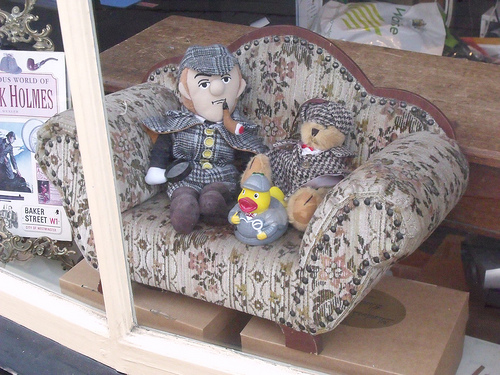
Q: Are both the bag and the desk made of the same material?
A: No, the bag is made of plastic and the desk is made of wood.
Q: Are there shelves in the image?
A: No, there are no shelves.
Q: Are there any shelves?
A: No, there are no shelves.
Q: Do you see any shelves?
A: No, there are no shelves.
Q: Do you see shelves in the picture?
A: No, there are no shelves.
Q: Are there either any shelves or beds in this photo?
A: No, there are no shelves or beds.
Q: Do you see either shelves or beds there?
A: No, there are no shelves or beds.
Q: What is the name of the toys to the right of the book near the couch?
A: The toys are stuffed animals.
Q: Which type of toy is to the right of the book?
A: The toys are stuffed animals.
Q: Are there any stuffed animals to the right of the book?
A: Yes, there are stuffed animals to the right of the book.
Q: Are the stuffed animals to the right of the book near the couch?
A: Yes, the stuffed animals are to the right of the book.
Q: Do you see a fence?
A: No, there are no fences.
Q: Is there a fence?
A: No, there are no fences.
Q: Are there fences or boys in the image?
A: No, there are no fences or boys.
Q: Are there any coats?
A: Yes, there is a coat.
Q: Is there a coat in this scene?
A: Yes, there is a coat.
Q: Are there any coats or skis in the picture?
A: Yes, there is a coat.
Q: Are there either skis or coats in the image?
A: Yes, there is a coat.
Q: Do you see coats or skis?
A: Yes, there is a coat.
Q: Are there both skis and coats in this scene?
A: No, there is a coat but no skis.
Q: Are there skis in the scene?
A: No, there are no skis.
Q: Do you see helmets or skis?
A: No, there are no skis or helmets.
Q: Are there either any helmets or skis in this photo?
A: No, there are no skis or helmets.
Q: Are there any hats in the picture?
A: Yes, there is a hat.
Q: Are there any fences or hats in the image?
A: Yes, there is a hat.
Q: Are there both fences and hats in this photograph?
A: No, there is a hat but no fences.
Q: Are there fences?
A: No, there are no fences.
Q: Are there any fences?
A: No, there are no fences.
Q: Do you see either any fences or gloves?
A: No, there are no fences or gloves.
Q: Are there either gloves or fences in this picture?
A: No, there are no fences or gloves.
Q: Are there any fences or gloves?
A: No, there are no fences or gloves.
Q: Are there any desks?
A: Yes, there is a desk.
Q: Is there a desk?
A: Yes, there is a desk.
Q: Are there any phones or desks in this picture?
A: Yes, there is a desk.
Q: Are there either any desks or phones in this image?
A: Yes, there is a desk.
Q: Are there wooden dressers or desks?
A: Yes, there is a wood desk.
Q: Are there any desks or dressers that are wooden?
A: Yes, the desk is wooden.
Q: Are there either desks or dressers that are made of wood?
A: Yes, the desk is made of wood.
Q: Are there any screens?
A: No, there are no screens.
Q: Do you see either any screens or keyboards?
A: No, there are no screens or keyboards.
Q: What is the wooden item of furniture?
A: The piece of furniture is a desk.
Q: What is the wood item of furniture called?
A: The piece of furniture is a desk.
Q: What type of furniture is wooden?
A: The furniture is a desk.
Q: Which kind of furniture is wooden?
A: The furniture is a desk.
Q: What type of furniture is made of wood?
A: The furniture is a desk.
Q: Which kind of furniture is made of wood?
A: The furniture is a desk.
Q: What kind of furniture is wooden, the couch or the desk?
A: The desk is wooden.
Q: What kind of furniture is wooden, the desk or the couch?
A: The desk is wooden.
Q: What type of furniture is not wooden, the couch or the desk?
A: The couch is not wooden.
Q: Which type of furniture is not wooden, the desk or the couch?
A: The couch is not wooden.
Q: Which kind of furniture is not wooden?
A: The furniture is a couch.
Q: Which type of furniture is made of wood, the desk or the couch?
A: The desk is made of wood.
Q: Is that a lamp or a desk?
A: That is a desk.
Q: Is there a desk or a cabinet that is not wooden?
A: No, there is a desk but it is wooden.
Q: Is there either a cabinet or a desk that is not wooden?
A: No, there is a desk but it is wooden.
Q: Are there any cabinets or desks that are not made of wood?
A: No, there is a desk but it is made of wood.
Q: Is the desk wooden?
A: Yes, the desk is wooden.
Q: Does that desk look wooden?
A: Yes, the desk is wooden.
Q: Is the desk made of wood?
A: Yes, the desk is made of wood.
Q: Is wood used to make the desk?
A: Yes, the desk is made of wood.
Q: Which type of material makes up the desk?
A: The desk is made of wood.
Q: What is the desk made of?
A: The desk is made of wood.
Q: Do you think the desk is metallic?
A: No, the desk is wooden.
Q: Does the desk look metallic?
A: No, the desk is wooden.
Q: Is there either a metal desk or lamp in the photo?
A: No, there is a desk but it is wooden.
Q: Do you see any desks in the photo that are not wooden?
A: No, there is a desk but it is wooden.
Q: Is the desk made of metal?
A: No, the desk is made of wood.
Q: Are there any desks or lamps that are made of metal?
A: No, there is a desk but it is made of wood.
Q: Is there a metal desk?
A: No, there is a desk but it is made of wood.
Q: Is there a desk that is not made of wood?
A: No, there is a desk but it is made of wood.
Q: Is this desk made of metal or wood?
A: The desk is made of wood.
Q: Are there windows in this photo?
A: Yes, there is a window.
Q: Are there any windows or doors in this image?
A: Yes, there is a window.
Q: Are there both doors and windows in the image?
A: No, there is a window but no doors.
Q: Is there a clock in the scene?
A: No, there are no clocks.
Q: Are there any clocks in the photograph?
A: No, there are no clocks.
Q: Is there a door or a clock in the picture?
A: No, there are no clocks or doors.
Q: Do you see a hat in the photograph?
A: Yes, there is a hat.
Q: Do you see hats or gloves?
A: Yes, there is a hat.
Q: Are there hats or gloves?
A: Yes, there is a hat.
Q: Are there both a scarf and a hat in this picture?
A: No, there is a hat but no scarves.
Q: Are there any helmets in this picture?
A: No, there are no helmets.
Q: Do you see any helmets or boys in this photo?
A: No, there are no helmets or boys.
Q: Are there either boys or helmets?
A: No, there are no helmets or boys.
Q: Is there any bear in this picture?
A: Yes, there is a bear.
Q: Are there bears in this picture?
A: Yes, there is a bear.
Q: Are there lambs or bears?
A: Yes, there is a bear.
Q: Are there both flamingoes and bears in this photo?
A: No, there is a bear but no flamingoes.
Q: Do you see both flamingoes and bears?
A: No, there is a bear but no flamingoes.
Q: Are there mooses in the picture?
A: No, there are no mooses.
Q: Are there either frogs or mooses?
A: No, there are no mooses or frogs.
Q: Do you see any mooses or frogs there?
A: No, there are no mooses or frogs.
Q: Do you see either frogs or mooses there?
A: No, there are no mooses or frogs.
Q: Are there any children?
A: No, there are no children.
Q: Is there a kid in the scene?
A: No, there are no children.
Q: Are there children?
A: No, there are no children.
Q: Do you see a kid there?
A: No, there are no children.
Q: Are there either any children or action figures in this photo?
A: No, there are no children or action figures.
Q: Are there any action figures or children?
A: No, there are no children or action figures.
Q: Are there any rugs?
A: No, there are no rugs.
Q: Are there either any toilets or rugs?
A: No, there are no rugs or toilets.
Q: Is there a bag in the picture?
A: Yes, there is a bag.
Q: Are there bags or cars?
A: Yes, there is a bag.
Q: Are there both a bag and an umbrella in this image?
A: No, there is a bag but no umbrellas.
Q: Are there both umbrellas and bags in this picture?
A: No, there is a bag but no umbrellas.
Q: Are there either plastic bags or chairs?
A: Yes, there is a plastic bag.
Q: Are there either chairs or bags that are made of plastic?
A: Yes, the bag is made of plastic.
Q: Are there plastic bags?
A: Yes, there is a bag that is made of plastic.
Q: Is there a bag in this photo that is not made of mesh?
A: Yes, there is a bag that is made of plastic.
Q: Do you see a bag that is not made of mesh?
A: Yes, there is a bag that is made of plastic.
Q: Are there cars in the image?
A: No, there are no cars.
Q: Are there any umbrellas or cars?
A: No, there are no cars or umbrellas.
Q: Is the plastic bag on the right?
A: Yes, the bag is on the right of the image.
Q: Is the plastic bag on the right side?
A: Yes, the bag is on the right of the image.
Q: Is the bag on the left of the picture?
A: No, the bag is on the right of the image.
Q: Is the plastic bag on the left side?
A: No, the bag is on the right of the image.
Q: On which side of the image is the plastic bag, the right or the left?
A: The bag is on the right of the image.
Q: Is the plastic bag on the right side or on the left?
A: The bag is on the right of the image.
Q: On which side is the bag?
A: The bag is on the right of the image.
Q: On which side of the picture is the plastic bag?
A: The bag is on the right of the image.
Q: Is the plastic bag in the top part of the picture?
A: Yes, the bag is in the top of the image.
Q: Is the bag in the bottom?
A: No, the bag is in the top of the image.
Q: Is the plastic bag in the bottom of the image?
A: No, the bag is in the top of the image.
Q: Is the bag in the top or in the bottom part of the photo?
A: The bag is in the top of the image.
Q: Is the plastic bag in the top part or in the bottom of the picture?
A: The bag is in the top of the image.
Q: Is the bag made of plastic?
A: Yes, the bag is made of plastic.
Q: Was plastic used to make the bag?
A: Yes, the bag is made of plastic.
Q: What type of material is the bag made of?
A: The bag is made of plastic.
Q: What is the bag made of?
A: The bag is made of plastic.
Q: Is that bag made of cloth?
A: No, the bag is made of plastic.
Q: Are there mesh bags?
A: No, there is a bag but it is made of plastic.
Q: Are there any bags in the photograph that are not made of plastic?
A: No, there is a bag but it is made of plastic.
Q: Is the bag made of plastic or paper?
A: The bag is made of plastic.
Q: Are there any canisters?
A: No, there are no canisters.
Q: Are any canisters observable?
A: No, there are no canisters.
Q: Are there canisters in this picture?
A: No, there are no canisters.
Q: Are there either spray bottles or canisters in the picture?
A: No, there are no canisters or spray bottles.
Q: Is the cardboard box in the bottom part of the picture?
A: Yes, the box is in the bottom of the image.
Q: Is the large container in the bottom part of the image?
A: Yes, the box is in the bottom of the image.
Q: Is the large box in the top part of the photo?
A: No, the box is in the bottom of the image.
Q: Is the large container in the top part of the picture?
A: No, the box is in the bottom of the image.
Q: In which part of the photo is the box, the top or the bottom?
A: The box is in the bottom of the image.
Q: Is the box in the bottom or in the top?
A: The box is in the bottom of the image.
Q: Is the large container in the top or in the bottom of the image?
A: The box is in the bottom of the image.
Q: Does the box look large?
A: Yes, the box is large.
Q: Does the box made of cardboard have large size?
A: Yes, the box is large.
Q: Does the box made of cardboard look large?
A: Yes, the box is large.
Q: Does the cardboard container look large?
A: Yes, the box is large.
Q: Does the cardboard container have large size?
A: Yes, the box is large.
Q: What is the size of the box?
A: The box is large.